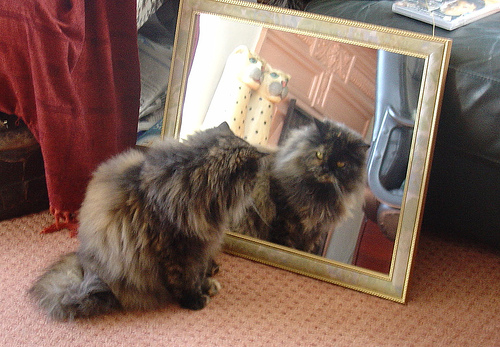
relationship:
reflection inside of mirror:
[234, 112, 376, 258] [175, 15, 425, 281]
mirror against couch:
[175, 15, 425, 281] [295, 2, 498, 266]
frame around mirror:
[161, 1, 455, 309] [175, 15, 425, 281]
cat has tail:
[20, 118, 280, 328] [20, 253, 127, 325]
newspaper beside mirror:
[137, 32, 175, 151] [175, 15, 425, 281]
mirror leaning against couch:
[175, 15, 425, 281] [295, 2, 498, 266]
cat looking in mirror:
[20, 118, 280, 328] [175, 15, 425, 281]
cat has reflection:
[20, 118, 280, 328] [234, 112, 376, 258]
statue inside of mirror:
[200, 41, 267, 141] [175, 15, 425, 281]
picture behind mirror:
[389, 2, 499, 36] [175, 15, 425, 281]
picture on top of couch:
[389, 2, 499, 36] [295, 2, 498, 266]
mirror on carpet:
[175, 15, 425, 281] [1, 214, 500, 346]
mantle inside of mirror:
[253, 23, 378, 271] [175, 15, 425, 281]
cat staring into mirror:
[20, 118, 280, 328] [175, 15, 425, 281]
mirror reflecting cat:
[175, 15, 425, 281] [20, 118, 280, 328]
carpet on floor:
[1, 214, 500, 346] [0, 201, 499, 344]